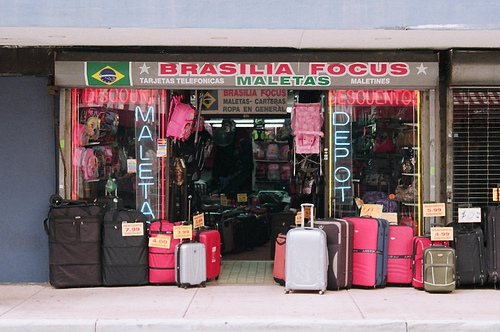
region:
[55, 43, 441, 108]
a store front sign.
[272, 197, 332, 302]
a silver piece of luggage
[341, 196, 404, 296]
a pink and black bag of luggage.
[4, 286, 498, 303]
a sidewalk in front of a store.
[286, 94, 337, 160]
a piece of luggage for sale.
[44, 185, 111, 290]
a black piece of luggage.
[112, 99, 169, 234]
a neon sign in a window.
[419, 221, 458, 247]
a sign above a bag.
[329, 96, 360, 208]
a blue neon sign.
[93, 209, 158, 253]
a price tag.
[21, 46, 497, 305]
Big brazillian luggage store.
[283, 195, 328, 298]
Grey luggage bag in front of store.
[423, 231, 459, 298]
Greenish luggage back in front of store.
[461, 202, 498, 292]
Black luggage bags in front of store.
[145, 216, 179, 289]
Pink duffle bag for luggage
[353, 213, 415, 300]
Pink luggages bags in front of store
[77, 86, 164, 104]
Discount sign in pink lettering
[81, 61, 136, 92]
Brazillian flag on left side of store front.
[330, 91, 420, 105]
Discount in pink lettering in spanish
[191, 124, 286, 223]
Dark inside of luggage store.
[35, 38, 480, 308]
A picture of a store selling luggage.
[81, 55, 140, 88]
Part of sign that's green, yellow and white.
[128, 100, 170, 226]
The word MALETA on store window.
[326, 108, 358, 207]
The word DEPOT on store window.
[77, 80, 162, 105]
The word DISCOUNT on store window.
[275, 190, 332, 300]
Tall silver luggage with wheels.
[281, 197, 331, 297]
Tall silver luggage with handle pulled up..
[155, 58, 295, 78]
The word BRASILIA on store front.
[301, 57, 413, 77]
The word FOCUS on store window.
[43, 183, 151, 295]
Two large black pieces of luggage.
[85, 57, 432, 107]
grey sign with red writing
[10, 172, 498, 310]
many different suitcases in front of store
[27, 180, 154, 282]
two black suitcases next to each other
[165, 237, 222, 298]
one white suitcase on left hand side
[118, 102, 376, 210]
two green neon signs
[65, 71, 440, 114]
two red neon signs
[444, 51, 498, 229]
gated store front to the righte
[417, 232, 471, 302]
one brown suitcase in photograph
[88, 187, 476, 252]
several price tags on suitcases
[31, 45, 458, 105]
red green and white lettering on store sign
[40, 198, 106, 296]
Large brown suitcase outside store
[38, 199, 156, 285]
large black suitcase next to brown suitcase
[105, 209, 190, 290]
Pink suitcase next to black suitcase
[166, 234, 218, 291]
small grey suitecase by pink suitcase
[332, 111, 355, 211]
Depot sign is blue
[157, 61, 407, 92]
Brasilia Focus written in red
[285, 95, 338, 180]
pink stroller hanging from doorway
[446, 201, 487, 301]
White sign on black suitcase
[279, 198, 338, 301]
large silver suitcase with handle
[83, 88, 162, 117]
Discount written in red